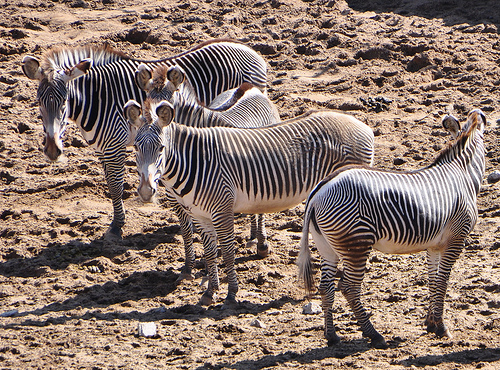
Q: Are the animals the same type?
A: Yes, all the animals are zebras.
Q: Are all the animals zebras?
A: Yes, all the animals are zebras.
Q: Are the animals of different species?
A: No, all the animals are zebras.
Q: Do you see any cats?
A: No, there are no cats.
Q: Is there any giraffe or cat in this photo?
A: No, there are no cats or giraffes.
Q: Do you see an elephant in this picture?
A: No, there are no elephants.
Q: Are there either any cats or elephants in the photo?
A: No, there are no elephants or cats.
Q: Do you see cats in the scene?
A: No, there are no cats.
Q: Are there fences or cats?
A: No, there are no cats or fences.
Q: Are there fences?
A: No, there are no fences.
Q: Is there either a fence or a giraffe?
A: No, there are no fences or giraffes.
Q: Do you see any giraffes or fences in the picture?
A: No, there are no fences or giraffes.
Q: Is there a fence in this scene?
A: No, there are no fences.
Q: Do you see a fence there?
A: No, there are no fences.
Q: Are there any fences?
A: No, there are no fences.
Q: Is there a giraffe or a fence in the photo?
A: No, there are no fences or giraffes.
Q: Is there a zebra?
A: Yes, there are zebras.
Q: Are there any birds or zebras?
A: Yes, there are zebras.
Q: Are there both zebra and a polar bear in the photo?
A: No, there are zebras but no polar bears.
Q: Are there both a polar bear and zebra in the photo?
A: No, there are zebras but no polar bears.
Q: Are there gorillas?
A: No, there are no gorillas.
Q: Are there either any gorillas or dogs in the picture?
A: No, there are no gorillas or dogs.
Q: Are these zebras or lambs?
A: These are zebras.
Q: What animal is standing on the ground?
A: The zebras are standing on the ground.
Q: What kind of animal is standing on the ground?
A: The animals are zebras.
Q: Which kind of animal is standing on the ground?
A: The animals are zebras.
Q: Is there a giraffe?
A: No, there are no giraffes.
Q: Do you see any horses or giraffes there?
A: No, there are no giraffes or horses.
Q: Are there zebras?
A: Yes, there is a zebra.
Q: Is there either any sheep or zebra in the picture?
A: Yes, there is a zebra.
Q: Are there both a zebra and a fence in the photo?
A: No, there is a zebra but no fences.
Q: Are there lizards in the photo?
A: No, there are no lizards.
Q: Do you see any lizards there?
A: No, there are no lizards.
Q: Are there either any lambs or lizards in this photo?
A: No, there are no lizards or lambs.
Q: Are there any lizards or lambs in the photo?
A: No, there are no lizards or lambs.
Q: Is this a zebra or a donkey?
A: This is a zebra.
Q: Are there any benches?
A: No, there are no benches.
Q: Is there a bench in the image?
A: No, there are no benches.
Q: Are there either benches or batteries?
A: No, there are no benches or batteries.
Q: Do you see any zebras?
A: Yes, there is a zebra.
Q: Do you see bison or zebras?
A: Yes, there is a zebra.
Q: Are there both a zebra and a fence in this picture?
A: No, there is a zebra but no fences.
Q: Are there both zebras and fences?
A: No, there is a zebra but no fences.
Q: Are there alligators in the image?
A: No, there are no alligators.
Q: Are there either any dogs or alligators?
A: No, there are no alligators or dogs.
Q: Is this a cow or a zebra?
A: This is a zebra.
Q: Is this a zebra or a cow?
A: This is a zebra.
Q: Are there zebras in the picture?
A: Yes, there is a zebra.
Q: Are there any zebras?
A: Yes, there is a zebra.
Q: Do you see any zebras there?
A: Yes, there is a zebra.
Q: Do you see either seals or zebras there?
A: Yes, there is a zebra.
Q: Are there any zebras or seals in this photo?
A: Yes, there is a zebra.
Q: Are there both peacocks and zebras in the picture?
A: No, there is a zebra but no peacocks.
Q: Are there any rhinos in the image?
A: No, there are no rhinos.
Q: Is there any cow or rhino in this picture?
A: No, there are no rhinos or cows.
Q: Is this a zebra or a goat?
A: This is a zebra.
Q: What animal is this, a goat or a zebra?
A: This is a zebra.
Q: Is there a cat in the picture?
A: No, there are no cats.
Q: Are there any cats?
A: No, there are no cats.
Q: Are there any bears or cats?
A: No, there are no cats or bears.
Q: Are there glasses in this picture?
A: No, there are no glasses.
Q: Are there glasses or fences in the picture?
A: No, there are no glasses or fences.